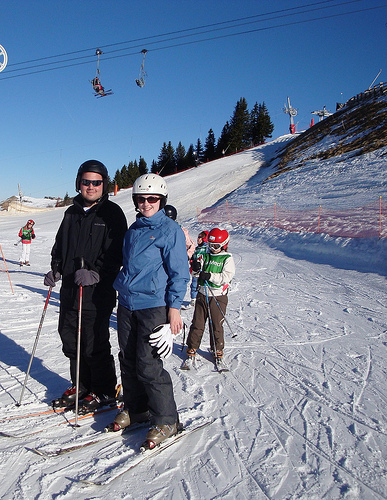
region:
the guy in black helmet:
[39, 160, 116, 216]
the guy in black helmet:
[44, 166, 162, 288]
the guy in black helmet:
[55, 106, 188, 338]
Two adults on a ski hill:
[43, 154, 192, 448]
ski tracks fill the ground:
[2, 269, 384, 495]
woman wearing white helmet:
[118, 168, 182, 223]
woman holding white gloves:
[119, 164, 191, 356]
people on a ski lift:
[75, 41, 122, 105]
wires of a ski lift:
[10, 1, 379, 78]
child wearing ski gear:
[182, 225, 241, 383]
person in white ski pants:
[11, 209, 35, 272]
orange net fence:
[184, 189, 385, 238]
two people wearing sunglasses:
[64, 158, 175, 224]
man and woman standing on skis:
[25, 148, 194, 459]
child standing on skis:
[181, 211, 232, 377]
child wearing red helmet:
[189, 219, 238, 377]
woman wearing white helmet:
[127, 167, 191, 317]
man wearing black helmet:
[63, 156, 117, 219]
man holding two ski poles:
[15, 157, 107, 432]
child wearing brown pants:
[189, 221, 233, 357]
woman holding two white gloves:
[115, 181, 190, 451]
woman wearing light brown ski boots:
[106, 180, 190, 461]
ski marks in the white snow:
[238, 341, 374, 491]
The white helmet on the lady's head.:
[126, 170, 168, 193]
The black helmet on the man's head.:
[69, 158, 104, 192]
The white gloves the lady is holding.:
[149, 315, 174, 357]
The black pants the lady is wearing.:
[108, 299, 177, 431]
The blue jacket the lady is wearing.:
[120, 210, 179, 305]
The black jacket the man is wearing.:
[48, 192, 126, 285]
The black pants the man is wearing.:
[48, 283, 132, 356]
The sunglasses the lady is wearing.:
[130, 190, 160, 200]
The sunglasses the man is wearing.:
[78, 176, 105, 187]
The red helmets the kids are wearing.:
[194, 226, 231, 251]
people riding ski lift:
[57, 32, 133, 118]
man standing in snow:
[45, 147, 129, 433]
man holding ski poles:
[42, 151, 123, 436]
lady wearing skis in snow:
[112, 167, 231, 467]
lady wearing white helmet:
[106, 158, 195, 277]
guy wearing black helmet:
[51, 138, 118, 229]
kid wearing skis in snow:
[193, 224, 241, 370]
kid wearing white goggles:
[190, 220, 240, 274]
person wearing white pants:
[14, 211, 57, 281]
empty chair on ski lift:
[120, 40, 167, 112]